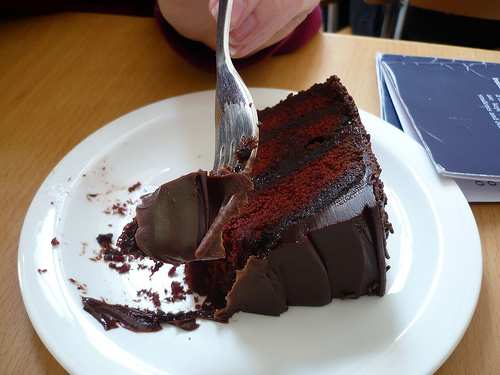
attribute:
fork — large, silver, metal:
[211, 0, 261, 175]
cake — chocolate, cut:
[138, 76, 387, 317]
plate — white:
[16, 87, 485, 373]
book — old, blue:
[376, 54, 499, 204]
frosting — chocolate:
[134, 170, 386, 323]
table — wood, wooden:
[1, 12, 499, 375]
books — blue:
[375, 53, 500, 200]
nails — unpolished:
[209, 1, 257, 55]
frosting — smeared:
[81, 181, 196, 329]